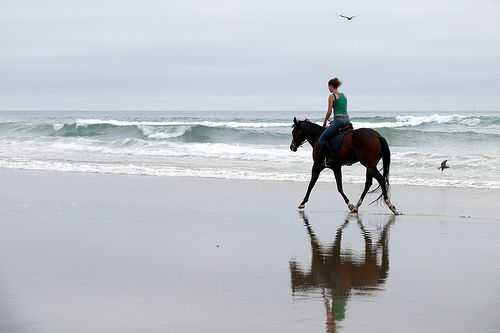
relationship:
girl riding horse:
[325, 75, 349, 129] [274, 117, 394, 187]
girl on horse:
[325, 75, 349, 129] [274, 117, 394, 187]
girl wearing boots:
[325, 75, 349, 129] [316, 136, 342, 170]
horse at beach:
[274, 117, 394, 187] [72, 20, 450, 226]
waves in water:
[110, 121, 245, 148] [73, 82, 295, 177]